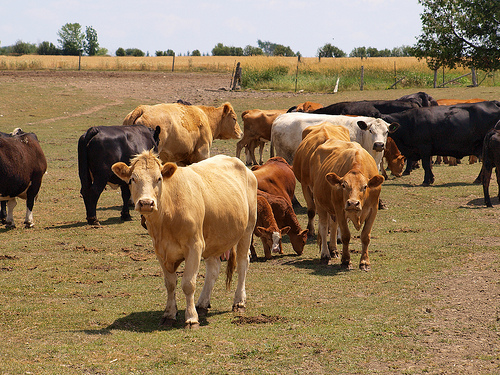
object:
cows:
[73, 115, 158, 231]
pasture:
[2, 56, 499, 374]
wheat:
[3, 56, 500, 73]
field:
[2, 52, 499, 374]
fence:
[231, 65, 494, 97]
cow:
[1, 128, 49, 228]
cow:
[267, 108, 391, 182]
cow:
[109, 155, 259, 322]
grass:
[7, 77, 499, 372]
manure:
[163, 83, 270, 107]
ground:
[1, 71, 500, 374]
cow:
[307, 136, 385, 275]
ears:
[320, 167, 346, 192]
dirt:
[26, 70, 254, 108]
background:
[4, 2, 500, 92]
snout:
[342, 196, 364, 213]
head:
[330, 168, 372, 219]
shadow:
[63, 301, 239, 350]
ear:
[158, 160, 179, 185]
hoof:
[230, 300, 251, 311]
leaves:
[429, 6, 500, 57]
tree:
[418, 0, 499, 81]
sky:
[1, 1, 497, 59]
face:
[120, 152, 169, 216]